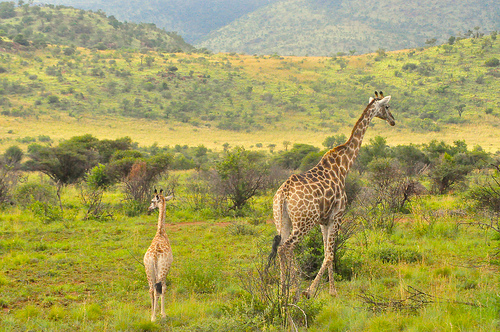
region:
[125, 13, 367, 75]
mountains filling the background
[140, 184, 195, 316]
smaller giraffe behind the larger one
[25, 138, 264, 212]
small trees growing behind the giraffes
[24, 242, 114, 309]
grass covered ground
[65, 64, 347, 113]
landscape dotted with small trees and shrubs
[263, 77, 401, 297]
larger giraffe is walking awa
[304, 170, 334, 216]
spots on the larger giraffe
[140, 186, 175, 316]
smaller giraffe is lighter in color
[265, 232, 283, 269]
long black hair at the end of the tail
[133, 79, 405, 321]
two giraffes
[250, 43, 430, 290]
the giraffe is walking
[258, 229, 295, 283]
giraffe's tail is black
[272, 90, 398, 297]
a tan and brown colored adult giraffe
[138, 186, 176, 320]
a juvenile giraffe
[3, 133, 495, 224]
small shrubs and trees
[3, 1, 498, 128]
rolling hills with green grass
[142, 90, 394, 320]
two walking giraffes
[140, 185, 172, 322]
a juvenile giraffe standing in the grass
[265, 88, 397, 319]
an adult giraffe walking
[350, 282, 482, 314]
a brown branch laying on the ground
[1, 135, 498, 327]
flat land full of vegetation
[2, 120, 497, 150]
yellow grass on flat land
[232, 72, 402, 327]
the giraffe is brown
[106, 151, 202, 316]
a baby giraffe in the field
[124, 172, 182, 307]
a baby giraffe in the field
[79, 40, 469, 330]
two giraffes in the wild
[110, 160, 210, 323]
a small brown giraffe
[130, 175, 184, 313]
a small brown giraffe